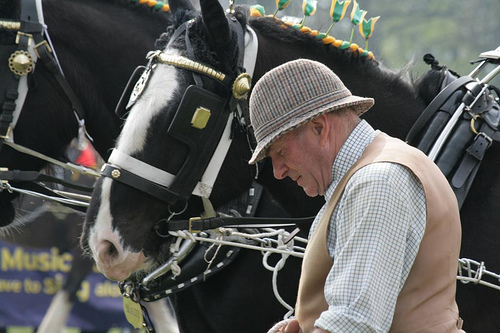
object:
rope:
[206, 218, 368, 298]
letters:
[16, 243, 41, 273]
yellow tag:
[110, 282, 155, 330]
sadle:
[402, 31, 497, 211]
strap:
[104, 147, 175, 189]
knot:
[262, 229, 295, 273]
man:
[239, 57, 466, 333]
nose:
[79, 232, 124, 267]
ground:
[308, 109, 395, 200]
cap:
[248, 57, 374, 158]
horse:
[78, 2, 458, 331]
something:
[122, 27, 249, 108]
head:
[64, 1, 270, 294]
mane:
[269, 0, 411, 63]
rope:
[188, 224, 498, 299]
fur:
[85, 73, 266, 287]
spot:
[136, 99, 155, 115]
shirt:
[300, 117, 454, 333]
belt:
[194, 150, 229, 202]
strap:
[116, 180, 261, 303]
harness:
[94, 2, 271, 304]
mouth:
[108, 225, 160, 283]